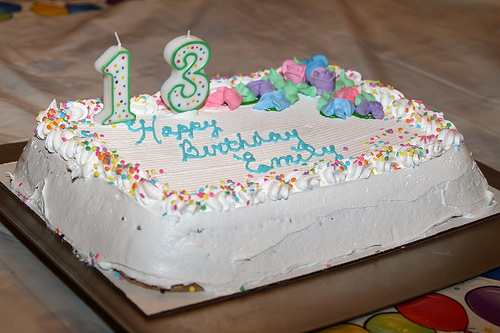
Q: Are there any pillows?
A: No, there are no pillows.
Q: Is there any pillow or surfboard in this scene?
A: No, there are no pillows or surfboards.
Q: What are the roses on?
A: The roses are on the cake.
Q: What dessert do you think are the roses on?
A: The roses are on the cake.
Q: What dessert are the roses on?
A: The roses are on the cake.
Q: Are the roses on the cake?
A: Yes, the roses are on the cake.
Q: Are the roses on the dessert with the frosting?
A: Yes, the roses are on the cake.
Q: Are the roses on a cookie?
A: No, the roses are on the cake.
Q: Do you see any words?
A: Yes, there are words.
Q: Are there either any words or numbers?
A: Yes, there are words.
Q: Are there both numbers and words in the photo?
A: Yes, there are both words and numbers.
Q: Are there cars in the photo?
A: No, there are no cars.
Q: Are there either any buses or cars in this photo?
A: No, there are no cars or buses.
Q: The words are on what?
A: The words are on the cake.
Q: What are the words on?
A: The words are on the cake.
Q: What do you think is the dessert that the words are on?
A: The dessert is a cake.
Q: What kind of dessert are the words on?
A: The words are on the cake.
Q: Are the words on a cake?
A: Yes, the words are on a cake.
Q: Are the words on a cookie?
A: No, the words are on a cake.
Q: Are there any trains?
A: No, there are no trains.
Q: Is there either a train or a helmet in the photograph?
A: No, there are no trains or helmets.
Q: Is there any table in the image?
A: Yes, there is a table.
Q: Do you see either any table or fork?
A: Yes, there is a table.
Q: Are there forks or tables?
A: Yes, there is a table.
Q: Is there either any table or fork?
A: Yes, there is a table.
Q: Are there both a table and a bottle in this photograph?
A: No, there is a table but no bottles.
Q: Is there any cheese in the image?
A: No, there is no cheese.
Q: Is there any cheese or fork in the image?
A: No, there are no cheese or forks.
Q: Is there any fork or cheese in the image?
A: No, there are no cheese or forks.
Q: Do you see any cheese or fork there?
A: No, there are no cheese or forks.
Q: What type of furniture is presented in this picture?
A: The furniture is a table.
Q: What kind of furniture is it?
A: The piece of furniture is a table.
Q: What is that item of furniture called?
A: This is a table.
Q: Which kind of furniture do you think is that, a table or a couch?
A: This is a table.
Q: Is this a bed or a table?
A: This is a table.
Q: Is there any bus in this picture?
A: No, there are no buses.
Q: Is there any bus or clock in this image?
A: No, there are no buses or clocks.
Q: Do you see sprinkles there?
A: Yes, there are sprinkles.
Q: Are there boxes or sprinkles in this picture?
A: Yes, there are sprinkles.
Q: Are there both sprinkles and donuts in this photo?
A: No, there are sprinkles but no donuts.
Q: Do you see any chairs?
A: No, there are no chairs.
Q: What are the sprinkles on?
A: The sprinkles are on the cake.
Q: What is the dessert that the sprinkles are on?
A: The dessert is a cake.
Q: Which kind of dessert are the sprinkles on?
A: The sprinkles are on the cake.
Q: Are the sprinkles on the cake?
A: Yes, the sprinkles are on the cake.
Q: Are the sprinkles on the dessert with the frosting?
A: Yes, the sprinkles are on the cake.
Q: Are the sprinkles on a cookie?
A: No, the sprinkles are on the cake.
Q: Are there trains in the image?
A: No, there are no trains.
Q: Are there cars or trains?
A: No, there are no trains or cars.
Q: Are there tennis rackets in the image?
A: No, there are no tennis rackets.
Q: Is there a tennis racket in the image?
A: No, there are no rackets.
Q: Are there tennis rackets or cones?
A: No, there are no tennis rackets or cones.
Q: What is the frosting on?
A: The frosting is on the cake.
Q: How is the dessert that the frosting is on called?
A: The dessert is a cake.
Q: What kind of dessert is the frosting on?
A: The frosting is on the cake.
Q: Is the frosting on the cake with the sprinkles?
A: Yes, the frosting is on the cake.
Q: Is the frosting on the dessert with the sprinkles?
A: Yes, the frosting is on the cake.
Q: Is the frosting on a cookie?
A: No, the frosting is on the cake.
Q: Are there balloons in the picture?
A: Yes, there is a balloon.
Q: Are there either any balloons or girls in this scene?
A: Yes, there is a balloon.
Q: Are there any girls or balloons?
A: Yes, there is a balloon.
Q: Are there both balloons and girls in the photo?
A: No, there is a balloon but no girls.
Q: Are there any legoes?
A: No, there are no legoes.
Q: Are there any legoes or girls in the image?
A: No, there are no legoes or girls.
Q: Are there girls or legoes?
A: No, there are no legoes or girls.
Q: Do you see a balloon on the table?
A: Yes, there is a balloon on the table.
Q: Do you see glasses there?
A: No, there are no glasses.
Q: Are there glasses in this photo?
A: No, there are no glasses.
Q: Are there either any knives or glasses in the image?
A: No, there are no glasses or knives.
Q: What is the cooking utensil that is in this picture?
A: The cooking utensil is a cake pan.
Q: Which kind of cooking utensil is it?
A: The cooking utensil is a cake pan.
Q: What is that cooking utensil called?
A: This is a cake pan.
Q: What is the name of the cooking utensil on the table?
A: The cooking utensil is a cake pan.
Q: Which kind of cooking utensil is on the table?
A: The cooking utensil is a cake pan.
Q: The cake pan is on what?
A: The cake pan is on the table.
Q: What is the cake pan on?
A: The cake pan is on the table.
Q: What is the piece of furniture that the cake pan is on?
A: The piece of furniture is a table.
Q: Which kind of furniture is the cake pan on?
A: The cake pan is on the table.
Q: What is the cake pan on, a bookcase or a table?
A: The cake pan is on a table.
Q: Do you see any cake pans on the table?
A: Yes, there is a cake pan on the table.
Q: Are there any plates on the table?
A: No, there is a cake pan on the table.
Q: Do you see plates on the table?
A: No, there is a cake pan on the table.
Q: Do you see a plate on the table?
A: No, there is a cake pan on the table.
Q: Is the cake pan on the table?
A: Yes, the cake pan is on the table.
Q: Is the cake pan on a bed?
A: No, the cake pan is on the table.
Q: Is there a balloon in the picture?
A: Yes, there is a balloon.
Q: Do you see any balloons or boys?
A: Yes, there is a balloon.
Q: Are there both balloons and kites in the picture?
A: No, there is a balloon but no kites.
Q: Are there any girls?
A: No, there are no girls.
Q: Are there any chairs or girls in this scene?
A: No, there are no girls or chairs.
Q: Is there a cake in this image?
A: Yes, there is a cake.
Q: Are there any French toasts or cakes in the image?
A: Yes, there is a cake.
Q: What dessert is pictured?
A: The dessert is a cake.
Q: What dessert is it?
A: The dessert is a cake.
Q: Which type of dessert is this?
A: This is a cake.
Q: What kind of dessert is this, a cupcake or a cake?
A: This is a cake.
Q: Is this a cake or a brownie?
A: This is a cake.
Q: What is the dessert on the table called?
A: The dessert is a cake.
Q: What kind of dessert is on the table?
A: The dessert is a cake.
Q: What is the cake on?
A: The cake is on the table.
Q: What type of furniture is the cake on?
A: The cake is on the table.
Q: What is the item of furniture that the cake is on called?
A: The piece of furniture is a table.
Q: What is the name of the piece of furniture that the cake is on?
A: The piece of furniture is a table.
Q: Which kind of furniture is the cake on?
A: The cake is on the table.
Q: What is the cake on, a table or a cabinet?
A: The cake is on a table.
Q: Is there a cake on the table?
A: Yes, there is a cake on the table.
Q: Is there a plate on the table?
A: No, there is a cake on the table.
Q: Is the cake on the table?
A: Yes, the cake is on the table.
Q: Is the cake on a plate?
A: No, the cake is on the table.